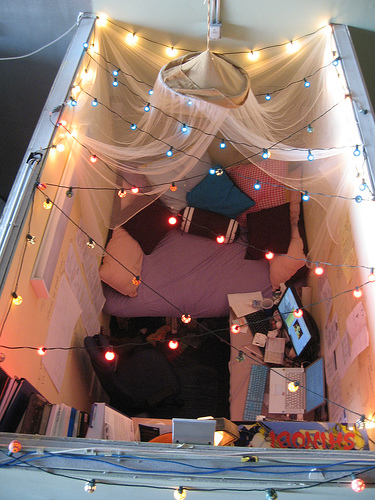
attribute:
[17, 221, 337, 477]
room — top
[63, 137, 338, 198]
netting — hung, mosquito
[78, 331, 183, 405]
chair — dark, grey, office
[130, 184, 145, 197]
light — red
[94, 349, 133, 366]
light — red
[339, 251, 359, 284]
paper — pinned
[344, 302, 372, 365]
paper — pinned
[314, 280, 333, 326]
paper — pinned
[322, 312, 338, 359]
paper — pinned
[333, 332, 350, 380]
paper — pinned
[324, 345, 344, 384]
paper — pinned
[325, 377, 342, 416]
paper — pinned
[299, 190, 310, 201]
light bulb — blue colored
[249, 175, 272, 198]
light bulb — blue colored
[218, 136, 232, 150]
blue bulb — blue colored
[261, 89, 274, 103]
light — blue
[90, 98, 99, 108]
light — blue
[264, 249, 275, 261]
light — red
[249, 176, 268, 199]
light bulb — blue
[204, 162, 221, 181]
light bulb — blue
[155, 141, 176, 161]
light bulb — blue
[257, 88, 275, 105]
light bulb — blue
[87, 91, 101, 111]
light bulb — blue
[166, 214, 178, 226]
light — red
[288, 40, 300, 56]
light bulb — blue colored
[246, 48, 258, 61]
light bulb — blue colored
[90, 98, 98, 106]
lightbulb — blue colored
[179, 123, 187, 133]
lightbulb — blue colored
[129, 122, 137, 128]
lightbulb — blue colored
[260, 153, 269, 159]
lightbulb — blue colored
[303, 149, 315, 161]
lightbulb — blue colored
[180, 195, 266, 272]
light — red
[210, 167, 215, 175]
light bulb — blue colored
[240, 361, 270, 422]
keyboard — grey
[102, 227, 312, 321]
sheet — light, purple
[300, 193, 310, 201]
light — blue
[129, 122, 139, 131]
light — blue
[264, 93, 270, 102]
light bulb — blue colored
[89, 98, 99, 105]
light bulb — blue colored